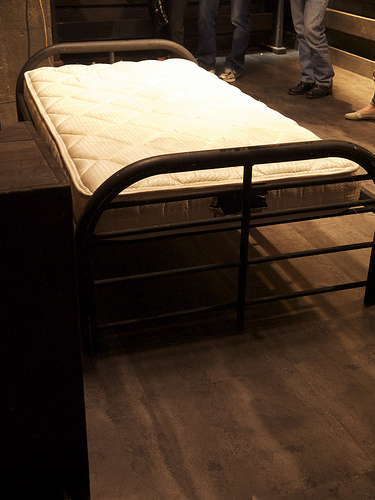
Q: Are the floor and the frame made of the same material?
A: No, the floor is made of cement and the frame is made of metal.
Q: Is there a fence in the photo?
A: No, there are no fences.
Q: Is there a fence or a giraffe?
A: No, there are no fences or giraffes.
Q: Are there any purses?
A: Yes, there is a purse.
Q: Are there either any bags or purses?
A: Yes, there is a purse.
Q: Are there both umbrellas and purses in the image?
A: No, there is a purse but no umbrellas.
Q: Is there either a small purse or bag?
A: Yes, there is a small purse.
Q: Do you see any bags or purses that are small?
A: Yes, the purse is small.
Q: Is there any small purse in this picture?
A: Yes, there is a small purse.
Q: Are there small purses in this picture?
A: Yes, there is a small purse.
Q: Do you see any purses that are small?
A: Yes, there is a purse that is small.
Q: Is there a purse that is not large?
A: Yes, there is a small purse.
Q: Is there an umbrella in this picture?
A: No, there are no umbrellas.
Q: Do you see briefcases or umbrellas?
A: No, there are no umbrellas or briefcases.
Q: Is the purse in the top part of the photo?
A: Yes, the purse is in the top of the image.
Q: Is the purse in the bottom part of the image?
A: No, the purse is in the top of the image.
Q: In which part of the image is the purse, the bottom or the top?
A: The purse is in the top of the image.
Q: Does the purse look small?
A: Yes, the purse is small.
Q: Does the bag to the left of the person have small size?
A: Yes, the purse is small.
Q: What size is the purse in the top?
A: The purse is small.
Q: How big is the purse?
A: The purse is small.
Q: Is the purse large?
A: No, the purse is small.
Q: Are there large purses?
A: No, there is a purse but it is small.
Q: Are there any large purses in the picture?
A: No, there is a purse but it is small.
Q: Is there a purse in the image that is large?
A: No, there is a purse but it is small.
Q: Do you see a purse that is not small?
A: No, there is a purse but it is small.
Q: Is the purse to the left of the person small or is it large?
A: The purse is small.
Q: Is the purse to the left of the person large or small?
A: The purse is small.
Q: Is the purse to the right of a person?
A: No, the purse is to the left of a person.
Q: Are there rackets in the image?
A: No, there are no rackets.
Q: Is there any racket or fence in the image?
A: No, there are no rackets or fences.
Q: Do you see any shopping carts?
A: No, there are no shopping carts.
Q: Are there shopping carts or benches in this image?
A: No, there are no shopping carts or benches.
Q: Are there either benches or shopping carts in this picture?
A: No, there are no shopping carts or benches.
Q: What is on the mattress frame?
A: The mattress is on the frame.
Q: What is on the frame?
A: The mattress is on the frame.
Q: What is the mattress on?
A: The mattress is on the frame.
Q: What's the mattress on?
A: The mattress is on the frame.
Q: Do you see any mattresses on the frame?
A: Yes, there is a mattress on the frame.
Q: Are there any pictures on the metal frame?
A: No, there is a mattress on the frame.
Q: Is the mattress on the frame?
A: Yes, the mattress is on the frame.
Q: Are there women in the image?
A: Yes, there is a woman.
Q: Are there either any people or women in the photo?
A: Yes, there is a woman.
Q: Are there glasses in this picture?
A: No, there are no glasses.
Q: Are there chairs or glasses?
A: No, there are no glasses or chairs.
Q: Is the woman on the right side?
A: Yes, the woman is on the right of the image.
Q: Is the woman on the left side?
A: No, the woman is on the right of the image.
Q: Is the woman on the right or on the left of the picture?
A: The woman is on the right of the image.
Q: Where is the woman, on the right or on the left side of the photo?
A: The woman is on the right of the image.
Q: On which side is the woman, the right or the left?
A: The woman is on the right of the image.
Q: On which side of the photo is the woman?
A: The woman is on the right of the image.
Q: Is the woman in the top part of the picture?
A: Yes, the woman is in the top of the image.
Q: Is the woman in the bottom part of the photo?
A: No, the woman is in the top of the image.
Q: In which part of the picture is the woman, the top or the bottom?
A: The woman is in the top of the image.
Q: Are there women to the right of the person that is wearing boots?
A: Yes, there is a woman to the right of the person.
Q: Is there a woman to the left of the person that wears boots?
A: No, the woman is to the right of the person.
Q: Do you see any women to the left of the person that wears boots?
A: No, the woman is to the right of the person.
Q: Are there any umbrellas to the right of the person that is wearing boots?
A: No, there is a woman to the right of the person.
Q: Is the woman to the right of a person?
A: Yes, the woman is to the right of a person.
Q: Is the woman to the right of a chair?
A: No, the woman is to the right of a person.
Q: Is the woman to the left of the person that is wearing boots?
A: No, the woman is to the right of the person.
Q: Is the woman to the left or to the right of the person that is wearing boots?
A: The woman is to the right of the person.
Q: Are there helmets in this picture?
A: No, there are no helmets.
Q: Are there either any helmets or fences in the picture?
A: No, there are no helmets or fences.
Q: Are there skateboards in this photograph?
A: No, there are no skateboards.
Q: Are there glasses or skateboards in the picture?
A: No, there are no skateboards or glasses.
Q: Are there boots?
A: Yes, there are boots.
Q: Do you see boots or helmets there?
A: Yes, there are boots.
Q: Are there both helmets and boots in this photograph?
A: No, there are boots but no helmets.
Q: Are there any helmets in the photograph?
A: No, there are no helmets.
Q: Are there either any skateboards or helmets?
A: No, there are no helmets or skateboards.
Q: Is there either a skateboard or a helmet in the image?
A: No, there are no helmets or skateboards.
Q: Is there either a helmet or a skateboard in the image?
A: No, there are no helmets or skateboards.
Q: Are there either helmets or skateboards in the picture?
A: No, there are no helmets or skateboards.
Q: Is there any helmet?
A: No, there are no helmets.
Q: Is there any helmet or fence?
A: No, there are no helmets or fences.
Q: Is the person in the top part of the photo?
A: Yes, the person is in the top of the image.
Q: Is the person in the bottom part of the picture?
A: No, the person is in the top of the image.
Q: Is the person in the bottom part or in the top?
A: The person is in the top of the image.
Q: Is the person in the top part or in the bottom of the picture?
A: The person is in the top of the image.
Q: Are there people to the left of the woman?
A: Yes, there is a person to the left of the woman.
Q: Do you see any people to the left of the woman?
A: Yes, there is a person to the left of the woman.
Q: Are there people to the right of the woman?
A: No, the person is to the left of the woman.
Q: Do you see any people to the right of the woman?
A: No, the person is to the left of the woman.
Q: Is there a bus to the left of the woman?
A: No, there is a person to the left of the woman.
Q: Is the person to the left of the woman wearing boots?
A: Yes, the person is wearing boots.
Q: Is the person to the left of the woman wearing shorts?
A: No, the person is wearing boots.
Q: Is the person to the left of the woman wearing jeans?
A: Yes, the person is wearing jeans.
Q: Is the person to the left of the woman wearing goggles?
A: No, the person is wearing jeans.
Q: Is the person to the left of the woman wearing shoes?
A: Yes, the person is wearing shoes.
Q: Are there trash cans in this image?
A: No, there are no trash cans.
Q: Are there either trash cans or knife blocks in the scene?
A: No, there are no trash cans or knife blocks.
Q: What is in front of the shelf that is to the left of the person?
A: The frame is in front of the shelf.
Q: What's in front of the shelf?
A: The frame is in front of the shelf.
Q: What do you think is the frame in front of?
A: The frame is in front of the shelf.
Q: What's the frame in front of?
A: The frame is in front of the shelf.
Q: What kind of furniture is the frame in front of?
A: The frame is in front of the shelf.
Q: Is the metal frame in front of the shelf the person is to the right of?
A: Yes, the frame is in front of the shelf.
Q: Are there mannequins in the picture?
A: No, there are no mannequins.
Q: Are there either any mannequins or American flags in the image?
A: No, there are no mannequins or American flags.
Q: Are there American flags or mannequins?
A: No, there are no mannequins or American flags.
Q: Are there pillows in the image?
A: No, there are no pillows.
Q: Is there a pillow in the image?
A: No, there are no pillows.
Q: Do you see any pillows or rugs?
A: No, there are no pillows or rugs.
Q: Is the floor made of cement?
A: Yes, the floor is made of cement.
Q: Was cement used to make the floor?
A: Yes, the floor is made of cement.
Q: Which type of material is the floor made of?
A: The floor is made of cement.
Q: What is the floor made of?
A: The floor is made of concrete.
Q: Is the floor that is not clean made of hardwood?
A: No, the floor is made of concrete.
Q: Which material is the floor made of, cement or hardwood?
A: The floor is made of cement.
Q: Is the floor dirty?
A: Yes, the floor is dirty.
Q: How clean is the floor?
A: The floor is dirty.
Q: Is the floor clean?
A: No, the floor is dirty.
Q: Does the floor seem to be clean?
A: No, the floor is dirty.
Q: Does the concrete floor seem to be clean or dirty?
A: The floor is dirty.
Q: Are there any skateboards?
A: No, there are no skateboards.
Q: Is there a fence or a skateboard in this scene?
A: No, there are no skateboards or fences.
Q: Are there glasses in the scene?
A: No, there are no glasses.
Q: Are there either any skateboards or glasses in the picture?
A: No, there are no glasses or skateboards.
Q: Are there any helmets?
A: No, there are no helmets.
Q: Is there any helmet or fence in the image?
A: No, there are no helmets or fences.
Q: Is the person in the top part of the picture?
A: Yes, the person is in the top of the image.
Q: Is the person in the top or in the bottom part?
A: The person is in the top of the image.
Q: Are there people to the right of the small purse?
A: Yes, there is a person to the right of the purse.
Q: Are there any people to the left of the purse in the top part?
A: No, the person is to the right of the purse.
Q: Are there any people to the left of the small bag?
A: No, the person is to the right of the purse.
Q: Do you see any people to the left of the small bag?
A: No, the person is to the right of the purse.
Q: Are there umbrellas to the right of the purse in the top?
A: No, there is a person to the right of the purse.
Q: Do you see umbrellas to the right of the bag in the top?
A: No, there is a person to the right of the purse.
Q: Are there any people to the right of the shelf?
A: Yes, there is a person to the right of the shelf.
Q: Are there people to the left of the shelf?
A: No, the person is to the right of the shelf.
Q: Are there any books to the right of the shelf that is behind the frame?
A: No, there is a person to the right of the shelf.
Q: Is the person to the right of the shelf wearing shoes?
A: Yes, the person is wearing shoes.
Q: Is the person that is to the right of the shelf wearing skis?
A: No, the person is wearing shoes.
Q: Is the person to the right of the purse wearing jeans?
A: Yes, the person is wearing jeans.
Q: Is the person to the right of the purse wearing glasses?
A: No, the person is wearing jeans.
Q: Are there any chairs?
A: No, there are no chairs.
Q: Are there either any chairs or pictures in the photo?
A: No, there are no chairs or pictures.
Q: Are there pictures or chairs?
A: No, there are no chairs or pictures.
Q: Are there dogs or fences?
A: No, there are no fences or dogs.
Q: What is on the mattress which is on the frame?
A: The tag is on the mattress.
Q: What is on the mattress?
A: The tag is on the mattress.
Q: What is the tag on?
A: The tag is on the mattress.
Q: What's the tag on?
A: The tag is on the mattress.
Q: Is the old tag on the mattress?
A: Yes, the tag is on the mattress.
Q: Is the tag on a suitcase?
A: No, the tag is on the mattress.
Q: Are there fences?
A: No, there are no fences.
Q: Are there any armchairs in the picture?
A: No, there are no armchairs.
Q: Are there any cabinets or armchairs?
A: No, there are no armchairs or cabinets.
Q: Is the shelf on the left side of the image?
A: Yes, the shelf is on the left of the image.